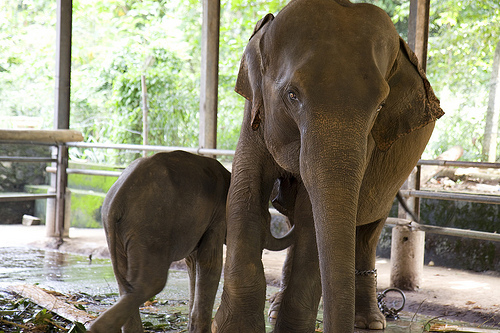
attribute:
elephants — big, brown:
[71, 3, 452, 332]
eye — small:
[284, 88, 300, 103]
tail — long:
[103, 210, 139, 295]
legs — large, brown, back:
[85, 234, 177, 332]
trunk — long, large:
[292, 130, 377, 332]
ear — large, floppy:
[235, 9, 278, 131]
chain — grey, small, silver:
[349, 264, 408, 322]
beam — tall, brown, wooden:
[56, 0, 76, 135]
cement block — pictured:
[391, 222, 427, 294]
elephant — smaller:
[70, 150, 233, 330]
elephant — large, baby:
[215, 3, 449, 328]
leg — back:
[348, 212, 388, 327]